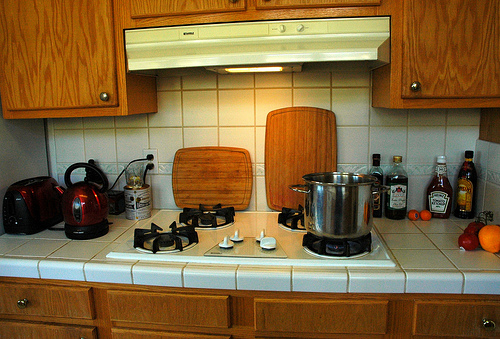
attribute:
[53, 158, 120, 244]
kettle — red, black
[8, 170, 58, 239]
toaster — red, black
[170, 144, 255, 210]
board — cutting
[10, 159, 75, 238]
toaster — red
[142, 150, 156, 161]
plug — black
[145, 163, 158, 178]
plug — black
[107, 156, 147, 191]
wire — black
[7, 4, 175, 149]
cabinets — wood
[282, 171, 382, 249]
pot — silver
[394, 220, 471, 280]
counter — kitchen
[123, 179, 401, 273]
stove — gas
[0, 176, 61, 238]
toaster — red, black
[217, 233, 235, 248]
knob — white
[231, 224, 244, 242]
knob — white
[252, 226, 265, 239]
knob — white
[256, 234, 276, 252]
knob — white